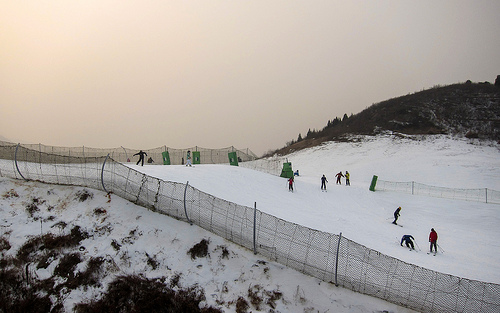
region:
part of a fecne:
[278, 231, 285, 238]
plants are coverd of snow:
[50, 209, 170, 310]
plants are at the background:
[380, 78, 445, 134]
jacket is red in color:
[422, 229, 444, 242]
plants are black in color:
[106, 244, 155, 310]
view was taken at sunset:
[113, 72, 298, 308]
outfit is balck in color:
[313, 162, 343, 202]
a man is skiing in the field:
[133, 139, 171, 176]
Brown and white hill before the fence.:
[1, 177, 402, 312]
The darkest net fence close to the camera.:
[1, 144, 498, 309]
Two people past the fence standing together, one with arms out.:
[331, 171, 351, 186]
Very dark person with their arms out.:
[132, 150, 148, 167]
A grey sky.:
[1, 1, 498, 147]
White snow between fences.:
[1, 156, 498, 293]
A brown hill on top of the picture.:
[298, 82, 499, 147]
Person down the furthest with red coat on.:
[428, 225, 438, 255]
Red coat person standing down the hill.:
[428, 227, 438, 253]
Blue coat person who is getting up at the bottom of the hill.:
[398, 233, 417, 250]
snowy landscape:
[0, 124, 498, 311]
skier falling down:
[395, 225, 421, 252]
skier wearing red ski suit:
[426, 223, 447, 257]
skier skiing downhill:
[387, 200, 413, 231]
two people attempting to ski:
[331, 169, 356, 187]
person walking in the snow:
[181, 149, 205, 173]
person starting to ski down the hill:
[132, 149, 154, 171]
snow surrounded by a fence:
[11, 133, 498, 310]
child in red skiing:
[286, 171, 303, 193]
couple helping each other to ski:
[332, 167, 356, 190]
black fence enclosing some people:
[0, 143, 496, 309]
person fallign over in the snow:
[397, 231, 418, 251]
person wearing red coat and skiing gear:
[425, 229, 446, 258]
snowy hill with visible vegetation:
[2, 180, 423, 311]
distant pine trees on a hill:
[286, 113, 353, 143]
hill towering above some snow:
[261, 74, 499, 165]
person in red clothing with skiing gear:
[283, 174, 298, 194]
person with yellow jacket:
[343, 169, 351, 185]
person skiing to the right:
[387, 204, 406, 229]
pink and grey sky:
[0, 2, 499, 154]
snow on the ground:
[12, 121, 473, 309]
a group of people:
[308, 161, 453, 271]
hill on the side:
[275, 50, 495, 191]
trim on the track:
[5, 131, 490, 311]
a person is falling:
[395, 226, 421, 256]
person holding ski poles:
[426, 237, 446, 254]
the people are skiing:
[385, 227, 441, 256]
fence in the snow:
[245, 228, 332, 272]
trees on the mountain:
[402, 108, 448, 128]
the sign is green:
[283, 163, 295, 176]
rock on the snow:
[179, 233, 211, 256]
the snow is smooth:
[293, 198, 342, 221]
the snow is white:
[457, 213, 479, 221]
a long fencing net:
[1, 139, 498, 202]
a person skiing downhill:
[400, 233, 422, 251]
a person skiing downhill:
[426, 226, 445, 257]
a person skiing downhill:
[390, 204, 404, 228]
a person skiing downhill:
[284, 172, 296, 192]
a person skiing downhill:
[319, 174, 327, 191]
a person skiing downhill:
[132, 149, 147, 165]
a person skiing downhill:
[183, 147, 195, 167]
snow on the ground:
[285, 188, 375, 223]